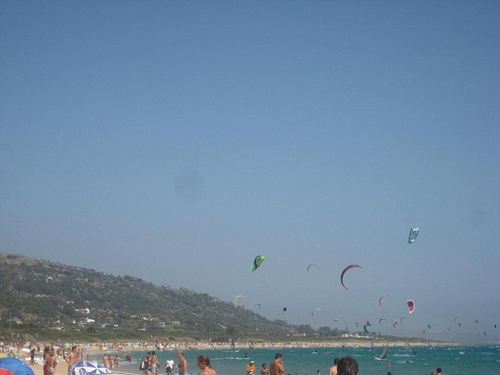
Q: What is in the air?
A: Kites.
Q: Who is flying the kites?
A: Beach goers.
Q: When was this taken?
A: During the day.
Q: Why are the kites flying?
A: There's wind.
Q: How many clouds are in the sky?
A: Zero.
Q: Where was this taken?
A: Beach.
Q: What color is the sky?
A: Blue.